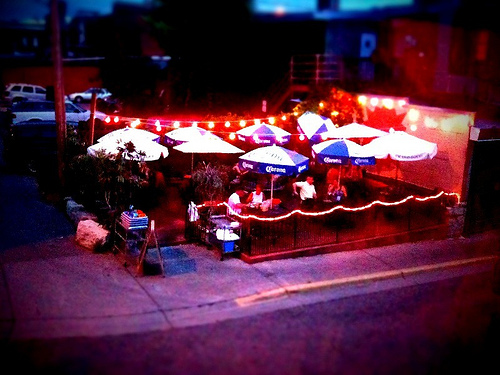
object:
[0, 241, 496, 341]
curb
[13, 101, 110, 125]
white truck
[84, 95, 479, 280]
outdoor cafe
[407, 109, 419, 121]
lights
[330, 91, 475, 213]
wall